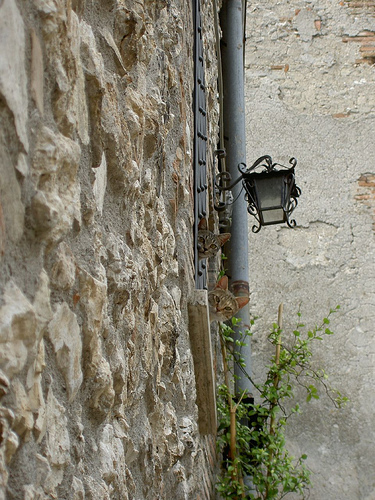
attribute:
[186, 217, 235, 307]
cats — looking, leaning, peering, furry, grey, brown, small, here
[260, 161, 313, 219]
lamp — black, hanging, here, off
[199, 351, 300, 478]
plant — growing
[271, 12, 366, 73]
wall — rocky, stone, here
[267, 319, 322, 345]
leaves — green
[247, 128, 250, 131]
pipe — mounted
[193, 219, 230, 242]
ears — pink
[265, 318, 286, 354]
leaf — green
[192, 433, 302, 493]
tree — here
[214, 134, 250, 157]
pole — here, metallic